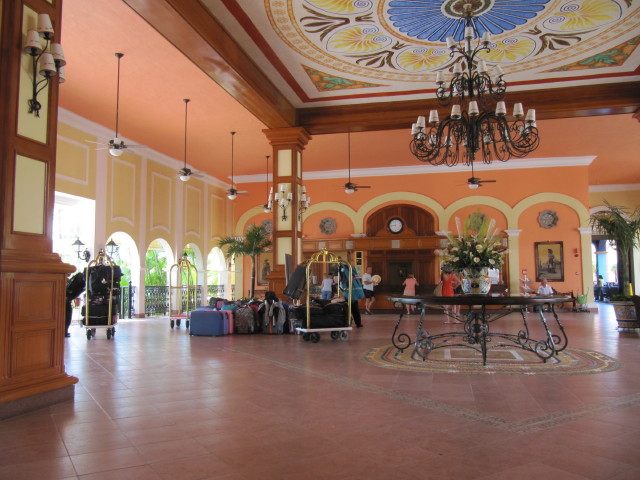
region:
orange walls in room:
[305, 145, 373, 196]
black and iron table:
[395, 293, 582, 360]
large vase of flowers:
[435, 224, 508, 283]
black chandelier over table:
[428, 43, 533, 189]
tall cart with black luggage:
[87, 255, 135, 337]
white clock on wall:
[366, 203, 430, 251]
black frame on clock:
[366, 209, 421, 250]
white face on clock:
[389, 212, 417, 241]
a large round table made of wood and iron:
[368, 277, 614, 385]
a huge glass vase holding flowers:
[434, 204, 517, 300]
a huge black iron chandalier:
[397, 57, 547, 167]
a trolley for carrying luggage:
[286, 232, 362, 349]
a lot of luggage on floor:
[181, 286, 288, 343]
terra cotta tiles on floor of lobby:
[171, 369, 349, 451]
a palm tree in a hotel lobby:
[595, 201, 638, 330]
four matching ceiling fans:
[96, 123, 277, 214]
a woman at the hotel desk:
[400, 264, 426, 313]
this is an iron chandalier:
[405, 20, 577, 187]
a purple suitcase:
[187, 301, 233, 345]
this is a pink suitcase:
[218, 304, 240, 332]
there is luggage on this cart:
[277, 235, 387, 370]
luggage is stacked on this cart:
[78, 231, 143, 348]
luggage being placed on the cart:
[62, 260, 90, 306]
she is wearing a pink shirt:
[397, 260, 428, 316]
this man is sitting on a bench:
[527, 272, 580, 315]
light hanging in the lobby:
[106, 137, 123, 157]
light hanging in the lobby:
[172, 169, 195, 181]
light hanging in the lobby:
[337, 177, 357, 198]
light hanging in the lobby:
[464, 180, 478, 187]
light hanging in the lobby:
[446, 99, 460, 119]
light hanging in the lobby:
[465, 98, 477, 118]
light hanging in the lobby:
[489, 96, 506, 119]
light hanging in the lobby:
[510, 99, 522, 120]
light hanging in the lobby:
[524, 104, 537, 128]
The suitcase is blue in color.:
[183, 307, 230, 338]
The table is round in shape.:
[385, 289, 577, 368]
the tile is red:
[69, 428, 123, 451]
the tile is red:
[144, 435, 203, 458]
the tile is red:
[404, 402, 427, 415]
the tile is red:
[553, 453, 594, 469]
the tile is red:
[537, 390, 571, 402]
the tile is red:
[435, 384, 468, 395]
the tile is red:
[336, 349, 359, 361]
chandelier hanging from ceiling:
[410, 2, 534, 170]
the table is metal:
[384, 294, 567, 364]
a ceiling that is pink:
[74, 26, 244, 168]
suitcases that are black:
[87, 266, 118, 322]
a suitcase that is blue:
[182, 306, 231, 342]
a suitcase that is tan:
[224, 299, 264, 341]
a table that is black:
[382, 284, 581, 377]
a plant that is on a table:
[448, 228, 504, 288]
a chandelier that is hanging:
[389, 54, 555, 183]